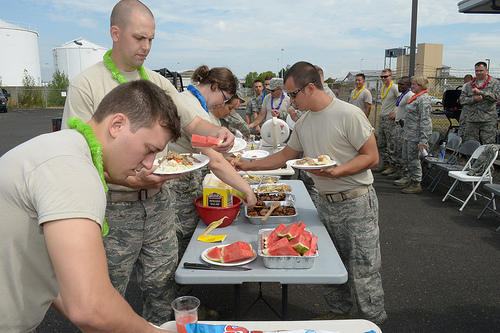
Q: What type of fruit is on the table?
A: Watermelon.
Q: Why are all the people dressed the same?
A: They are in the military.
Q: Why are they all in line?
A: To eat.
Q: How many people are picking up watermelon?
A: One man.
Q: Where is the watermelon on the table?
A: In the lower right.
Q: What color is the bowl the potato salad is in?
A: Red.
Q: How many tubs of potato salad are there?
A: One.